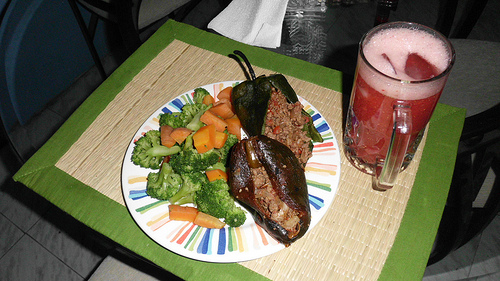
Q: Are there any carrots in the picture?
A: Yes, there is a carrot.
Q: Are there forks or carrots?
A: Yes, there is a carrot.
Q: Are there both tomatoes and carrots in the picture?
A: Yes, there are both a carrot and a tomato.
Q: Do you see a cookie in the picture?
A: No, there are no cookies.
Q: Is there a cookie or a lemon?
A: No, there are no cookies or lemons.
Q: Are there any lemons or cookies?
A: No, there are no cookies or lemons.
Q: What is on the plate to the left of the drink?
A: The carrot is on the plate.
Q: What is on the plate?
A: The carrot is on the plate.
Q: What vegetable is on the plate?
A: The vegetable is a carrot.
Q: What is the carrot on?
A: The carrot is on the plate.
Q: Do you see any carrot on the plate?
A: Yes, there is a carrot on the plate.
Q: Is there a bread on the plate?
A: No, there is a carrot on the plate.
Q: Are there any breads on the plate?
A: No, there is a carrot on the plate.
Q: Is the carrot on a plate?
A: Yes, the carrot is on a plate.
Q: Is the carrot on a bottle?
A: No, the carrot is on a plate.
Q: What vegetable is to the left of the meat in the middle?
A: The vegetable is a carrot.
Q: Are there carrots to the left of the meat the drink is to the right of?
A: Yes, there is a carrot to the left of the meat.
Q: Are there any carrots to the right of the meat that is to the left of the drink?
A: No, the carrot is to the left of the meat.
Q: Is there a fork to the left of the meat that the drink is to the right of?
A: No, there is a carrot to the left of the meat.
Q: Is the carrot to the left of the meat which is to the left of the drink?
A: Yes, the carrot is to the left of the meat.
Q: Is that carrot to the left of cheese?
A: No, the carrot is to the left of the meat.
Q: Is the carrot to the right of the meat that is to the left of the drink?
A: No, the carrot is to the left of the meat.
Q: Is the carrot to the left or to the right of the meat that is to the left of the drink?
A: The carrot is to the left of the meat.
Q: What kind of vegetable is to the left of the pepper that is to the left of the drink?
A: The vegetable is a carrot.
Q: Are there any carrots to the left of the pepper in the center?
A: Yes, there is a carrot to the left of the pepper.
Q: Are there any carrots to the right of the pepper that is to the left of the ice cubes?
A: No, the carrot is to the left of the pepper.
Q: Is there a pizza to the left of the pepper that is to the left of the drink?
A: No, there is a carrot to the left of the pepper.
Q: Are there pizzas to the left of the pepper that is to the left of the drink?
A: No, there is a carrot to the left of the pepper.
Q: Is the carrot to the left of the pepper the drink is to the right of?
A: Yes, the carrot is to the left of the pepper.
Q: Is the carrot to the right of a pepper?
A: No, the carrot is to the left of a pepper.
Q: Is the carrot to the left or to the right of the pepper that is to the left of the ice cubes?
A: The carrot is to the left of the pepper.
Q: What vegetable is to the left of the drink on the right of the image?
A: The vegetable is a carrot.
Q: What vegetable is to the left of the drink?
A: The vegetable is a carrot.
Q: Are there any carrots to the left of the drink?
A: Yes, there is a carrot to the left of the drink.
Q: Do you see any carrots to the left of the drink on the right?
A: Yes, there is a carrot to the left of the drink.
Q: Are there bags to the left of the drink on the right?
A: No, there is a carrot to the left of the drink.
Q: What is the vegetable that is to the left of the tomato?
A: The vegetable is a carrot.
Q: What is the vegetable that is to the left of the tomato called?
A: The vegetable is a carrot.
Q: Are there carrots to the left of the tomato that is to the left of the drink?
A: Yes, there is a carrot to the left of the tomato.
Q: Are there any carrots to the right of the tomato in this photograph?
A: No, the carrot is to the left of the tomato.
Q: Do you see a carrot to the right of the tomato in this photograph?
A: No, the carrot is to the left of the tomato.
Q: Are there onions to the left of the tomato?
A: No, there is a carrot to the left of the tomato.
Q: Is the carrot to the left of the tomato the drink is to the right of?
A: Yes, the carrot is to the left of the tomato.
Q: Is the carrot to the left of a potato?
A: No, the carrot is to the left of the tomato.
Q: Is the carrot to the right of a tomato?
A: No, the carrot is to the left of a tomato.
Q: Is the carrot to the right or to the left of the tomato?
A: The carrot is to the left of the tomato.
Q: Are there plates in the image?
A: Yes, there is a plate.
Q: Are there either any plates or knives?
A: Yes, there is a plate.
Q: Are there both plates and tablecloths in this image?
A: No, there is a plate but no tablecloths.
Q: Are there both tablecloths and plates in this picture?
A: No, there is a plate but no tablecloths.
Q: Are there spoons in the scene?
A: No, there are no spoons.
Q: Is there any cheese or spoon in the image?
A: No, there are no spoons or cheese.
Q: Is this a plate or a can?
A: This is a plate.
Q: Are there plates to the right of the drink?
A: No, the plate is to the left of the drink.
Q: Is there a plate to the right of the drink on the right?
A: No, the plate is to the left of the drink.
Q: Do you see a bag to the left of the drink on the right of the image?
A: No, there is a plate to the left of the drink.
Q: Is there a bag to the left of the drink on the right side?
A: No, there is a plate to the left of the drink.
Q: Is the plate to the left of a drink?
A: Yes, the plate is to the left of a drink.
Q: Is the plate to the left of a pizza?
A: No, the plate is to the left of a drink.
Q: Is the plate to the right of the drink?
A: No, the plate is to the left of the drink.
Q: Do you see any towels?
A: Yes, there is a towel.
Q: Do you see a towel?
A: Yes, there is a towel.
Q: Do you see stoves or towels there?
A: Yes, there is a towel.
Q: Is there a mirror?
A: No, there are no mirrors.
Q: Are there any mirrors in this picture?
A: No, there are no mirrors.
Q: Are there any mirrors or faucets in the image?
A: No, there are no mirrors or faucets.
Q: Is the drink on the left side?
A: No, the drink is on the right of the image.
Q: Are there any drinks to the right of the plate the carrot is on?
A: Yes, there is a drink to the right of the plate.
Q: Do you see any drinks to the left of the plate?
A: No, the drink is to the right of the plate.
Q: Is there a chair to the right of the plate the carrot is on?
A: No, there is a drink to the right of the plate.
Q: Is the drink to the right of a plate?
A: Yes, the drink is to the right of a plate.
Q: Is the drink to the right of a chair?
A: No, the drink is to the right of a plate.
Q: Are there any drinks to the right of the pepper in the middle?
A: Yes, there is a drink to the right of the pepper.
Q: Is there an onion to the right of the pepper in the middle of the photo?
A: No, there is a drink to the right of the pepper.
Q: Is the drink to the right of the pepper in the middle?
A: Yes, the drink is to the right of the pepper.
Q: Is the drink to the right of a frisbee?
A: No, the drink is to the right of the pepper.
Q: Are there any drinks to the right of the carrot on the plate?
A: Yes, there is a drink to the right of the carrot.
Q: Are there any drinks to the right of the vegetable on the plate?
A: Yes, there is a drink to the right of the carrot.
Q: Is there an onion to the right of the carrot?
A: No, there is a drink to the right of the carrot.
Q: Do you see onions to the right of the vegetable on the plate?
A: No, there is a drink to the right of the carrot.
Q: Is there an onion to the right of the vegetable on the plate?
A: No, there is a drink to the right of the carrot.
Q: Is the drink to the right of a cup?
A: No, the drink is to the right of the carrot.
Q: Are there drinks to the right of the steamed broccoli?
A: Yes, there is a drink to the right of the broccoli.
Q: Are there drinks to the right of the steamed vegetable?
A: Yes, there is a drink to the right of the broccoli.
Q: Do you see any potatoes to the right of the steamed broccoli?
A: No, there is a drink to the right of the broccoli.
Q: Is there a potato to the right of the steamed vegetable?
A: No, there is a drink to the right of the broccoli.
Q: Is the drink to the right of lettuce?
A: No, the drink is to the right of the broccoli.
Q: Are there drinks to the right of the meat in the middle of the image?
A: Yes, there is a drink to the right of the meat.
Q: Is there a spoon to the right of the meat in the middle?
A: No, there is a drink to the right of the meat.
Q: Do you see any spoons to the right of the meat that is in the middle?
A: No, there is a drink to the right of the meat.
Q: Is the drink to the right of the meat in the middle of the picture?
A: Yes, the drink is to the right of the meat.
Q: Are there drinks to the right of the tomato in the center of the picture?
A: Yes, there is a drink to the right of the tomato.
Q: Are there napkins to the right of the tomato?
A: No, there is a drink to the right of the tomato.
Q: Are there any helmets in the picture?
A: No, there are no helmets.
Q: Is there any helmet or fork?
A: No, there are no helmets or forks.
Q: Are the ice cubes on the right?
A: Yes, the ice cubes are on the right of the image.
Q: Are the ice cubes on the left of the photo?
A: No, the ice cubes are on the right of the image.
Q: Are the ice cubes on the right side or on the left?
A: The ice cubes are on the right of the image.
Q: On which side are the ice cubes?
A: The ice cubes are on the right of the image.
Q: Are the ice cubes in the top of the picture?
A: Yes, the ice cubes are in the top of the image.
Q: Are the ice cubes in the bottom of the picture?
A: No, the ice cubes are in the top of the image.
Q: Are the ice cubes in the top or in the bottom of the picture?
A: The ice cubes are in the top of the image.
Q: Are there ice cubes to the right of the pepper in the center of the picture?
A: Yes, there are ice cubes to the right of the pepper.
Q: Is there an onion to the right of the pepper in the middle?
A: No, there are ice cubes to the right of the pepper.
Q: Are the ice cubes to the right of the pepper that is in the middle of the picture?
A: Yes, the ice cubes are to the right of the pepper.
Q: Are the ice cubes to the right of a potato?
A: No, the ice cubes are to the right of the pepper.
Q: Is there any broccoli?
A: Yes, there is broccoli.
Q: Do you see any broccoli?
A: Yes, there is broccoli.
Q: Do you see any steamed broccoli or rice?
A: Yes, there is steamed broccoli.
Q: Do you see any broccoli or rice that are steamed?
A: Yes, the broccoli is steamed.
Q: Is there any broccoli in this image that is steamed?
A: Yes, there is steamed broccoli.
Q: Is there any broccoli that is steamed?
A: Yes, there is broccoli that is steamed.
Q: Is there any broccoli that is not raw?
A: Yes, there is steamed broccoli.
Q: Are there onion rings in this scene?
A: No, there are no onion rings.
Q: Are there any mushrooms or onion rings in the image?
A: No, there are no onion rings or mushrooms.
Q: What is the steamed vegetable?
A: The vegetable is broccoli.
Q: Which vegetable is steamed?
A: The vegetable is broccoli.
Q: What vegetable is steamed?
A: The vegetable is broccoli.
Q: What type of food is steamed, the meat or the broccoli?
A: The broccoli is steamed.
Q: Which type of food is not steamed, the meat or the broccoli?
A: The meat is not steamed.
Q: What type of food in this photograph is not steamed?
A: The food is meat.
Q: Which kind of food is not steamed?
A: The food is meat.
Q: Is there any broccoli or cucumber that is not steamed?
A: No, there is broccoli but it is steamed.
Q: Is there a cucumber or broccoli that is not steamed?
A: No, there is broccoli but it is steamed.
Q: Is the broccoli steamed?
A: Yes, the broccoli is steamed.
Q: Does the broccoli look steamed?
A: Yes, the broccoli is steamed.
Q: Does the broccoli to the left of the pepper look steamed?
A: Yes, the broccoli is steamed.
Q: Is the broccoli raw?
A: No, the broccoli is steamed.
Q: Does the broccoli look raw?
A: No, the broccoli is steamed.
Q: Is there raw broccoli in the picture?
A: No, there is broccoli but it is steamed.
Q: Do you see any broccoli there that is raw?
A: No, there is broccoli but it is steamed.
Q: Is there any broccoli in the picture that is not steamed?
A: No, there is broccoli but it is steamed.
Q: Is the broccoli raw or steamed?
A: The broccoli is steamed.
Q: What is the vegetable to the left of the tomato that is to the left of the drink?
A: The vegetable is broccoli.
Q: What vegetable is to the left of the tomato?
A: The vegetable is broccoli.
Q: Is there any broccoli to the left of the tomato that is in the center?
A: Yes, there is broccoli to the left of the tomato.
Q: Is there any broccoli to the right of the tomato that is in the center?
A: No, the broccoli is to the left of the tomato.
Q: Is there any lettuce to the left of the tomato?
A: No, there is broccoli to the left of the tomato.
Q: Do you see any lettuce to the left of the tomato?
A: No, there is broccoli to the left of the tomato.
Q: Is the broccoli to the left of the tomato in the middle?
A: Yes, the broccoli is to the left of the tomato.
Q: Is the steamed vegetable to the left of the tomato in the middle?
A: Yes, the broccoli is to the left of the tomato.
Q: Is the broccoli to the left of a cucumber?
A: No, the broccoli is to the left of the tomato.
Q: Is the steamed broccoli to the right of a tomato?
A: No, the broccoli is to the left of a tomato.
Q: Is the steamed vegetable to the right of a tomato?
A: No, the broccoli is to the left of a tomato.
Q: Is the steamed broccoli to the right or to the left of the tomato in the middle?
A: The broccoli is to the left of the tomato.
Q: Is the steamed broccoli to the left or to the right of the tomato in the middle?
A: The broccoli is to the left of the tomato.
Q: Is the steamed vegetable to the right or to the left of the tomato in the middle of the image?
A: The broccoli is to the left of the tomato.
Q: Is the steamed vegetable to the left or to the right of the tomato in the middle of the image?
A: The broccoli is to the left of the tomato.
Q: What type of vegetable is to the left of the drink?
A: The vegetable is broccoli.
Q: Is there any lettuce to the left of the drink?
A: No, there is broccoli to the left of the drink.